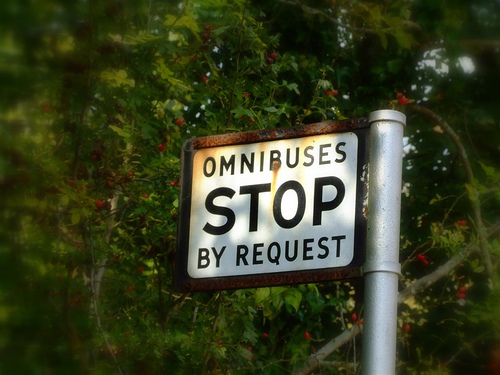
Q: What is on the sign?
A: The word stop.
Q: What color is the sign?
A: White.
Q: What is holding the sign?
A: A pole.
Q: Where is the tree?
A: Behind the sign.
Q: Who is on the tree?
A: Red berries.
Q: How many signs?
A: One.